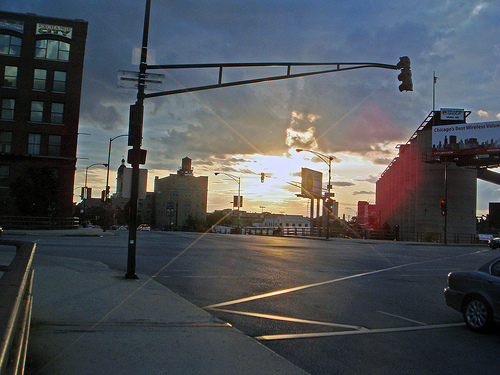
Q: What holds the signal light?
A: Black metal arm over street.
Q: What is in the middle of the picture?
A: Street light overlooking street.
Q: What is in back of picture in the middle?
A: Sun shining through clouds.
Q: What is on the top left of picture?
A: Dark warehouse with windows.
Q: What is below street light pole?
A: Sidewalk next to road.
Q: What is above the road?
A: Black metal traffic light supports.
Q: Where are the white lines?
A: Street.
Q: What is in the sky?
A: Clouds.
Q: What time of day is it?
A: Evening.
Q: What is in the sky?
A: Sun.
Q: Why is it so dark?
A: Sun is going down.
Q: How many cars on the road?
A: One.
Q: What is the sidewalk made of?
A: Concrete.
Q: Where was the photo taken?
A: City street.